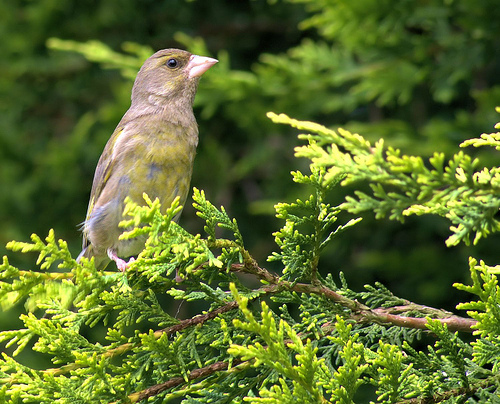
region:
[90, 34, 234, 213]
this is a bird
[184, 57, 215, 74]
this is the beak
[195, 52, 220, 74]
the beak is sharp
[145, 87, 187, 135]
the bird is brown in color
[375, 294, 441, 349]
this is a branch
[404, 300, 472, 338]
the branch is weak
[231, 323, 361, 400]
the branch is leafy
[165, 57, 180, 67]
this is the eye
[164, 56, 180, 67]
the eye is black in color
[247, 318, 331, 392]
the leaves are green in color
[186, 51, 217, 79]
A white beak on a bird.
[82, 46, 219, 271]
A small bird with feathers and a black eye.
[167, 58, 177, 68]
Little black eye of a bird.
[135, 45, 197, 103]
Head of a bird with a black eye.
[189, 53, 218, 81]
Light pink beak on a birds face.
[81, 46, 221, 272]
A brown, green and blue bird with a black eye.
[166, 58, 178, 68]
A black eye on a bird.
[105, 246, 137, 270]
Visible foot of a bird.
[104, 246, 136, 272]
Small pink visible leg of a bird.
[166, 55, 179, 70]
black eye of bird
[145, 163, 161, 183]
blue light on bird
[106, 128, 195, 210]
yellow feathers on bird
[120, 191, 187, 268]
yellow light on green branches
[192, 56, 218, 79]
beige beak of brown bird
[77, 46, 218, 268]
brown bird sitting on branch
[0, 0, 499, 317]
blurry branches on background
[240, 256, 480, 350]
prominent brown branch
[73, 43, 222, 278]
right side of bird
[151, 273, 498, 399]
green branches under yellowish branches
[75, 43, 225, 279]
blue yellow and brown bird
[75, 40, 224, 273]
small bird facing right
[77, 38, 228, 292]
bird looking to the right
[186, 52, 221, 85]
small pink bird beak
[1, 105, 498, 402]
thin green and brown tree branches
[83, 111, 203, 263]
bird wing with blue spots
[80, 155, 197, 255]
blue spots on wing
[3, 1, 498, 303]
green trees in background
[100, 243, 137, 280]
bird talon clutching branch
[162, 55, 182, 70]
small black bird eye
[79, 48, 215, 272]
brown bird on top of a branch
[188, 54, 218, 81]
pointy tan colored beak on head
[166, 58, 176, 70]
dark beady little eye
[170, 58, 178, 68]
eye to the left of beak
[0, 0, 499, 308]
green trees behind the bird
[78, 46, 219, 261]
bird in front of trees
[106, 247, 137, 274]
foot under bird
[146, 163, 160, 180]
grayish blue mark on chest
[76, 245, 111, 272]
tail feather visible behind the bird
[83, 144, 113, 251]
bird has a wing